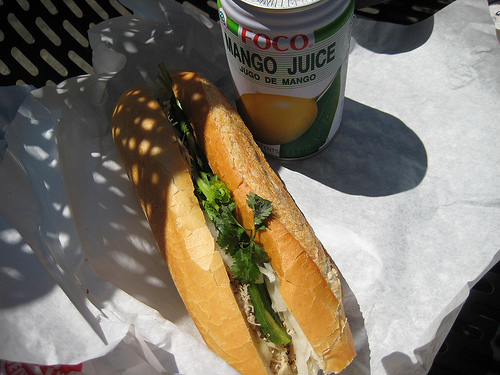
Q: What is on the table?
A: A sandwich.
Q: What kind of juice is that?
A: Mango.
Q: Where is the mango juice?
A: Next to the sandwich.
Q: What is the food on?
A: White paper.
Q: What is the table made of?
A: Metal.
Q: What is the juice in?
A: A can.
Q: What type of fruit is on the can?
A: A mango.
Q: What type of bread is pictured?
A: White bread.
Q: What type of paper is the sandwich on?
A: Parchment paper.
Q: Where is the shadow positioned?
A: To the left of the can.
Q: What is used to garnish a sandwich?
A: A sprig of a herb.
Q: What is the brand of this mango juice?
A: Foco.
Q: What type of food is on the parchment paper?
A: A sandwich.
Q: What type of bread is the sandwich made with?
A: Toasted bread.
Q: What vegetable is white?
A: Onion.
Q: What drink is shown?
A: Mango juice.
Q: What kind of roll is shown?
A: Hoagie.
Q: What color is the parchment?
A: White.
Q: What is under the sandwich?
A: White paper.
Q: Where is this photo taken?
A: Outside on a park bench.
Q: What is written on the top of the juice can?
A: FOCO.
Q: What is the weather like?
A: Sunny.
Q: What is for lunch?
A: Sandwich.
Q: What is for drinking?
A: Juice.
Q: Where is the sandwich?
A: On the paper.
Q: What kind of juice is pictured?
A: Mango.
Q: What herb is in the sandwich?
A: Cilantro.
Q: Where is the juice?
A: Next to the sandwich.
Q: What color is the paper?
A: White.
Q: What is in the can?
A: Mango juice.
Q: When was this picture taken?
A: Daytime.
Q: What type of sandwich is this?
A: Sub.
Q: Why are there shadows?
A: It's sunny.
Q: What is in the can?
A: Mango juice.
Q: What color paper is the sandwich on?
A: White.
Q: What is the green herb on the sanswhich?
A: Parsley.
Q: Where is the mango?
A: On can.